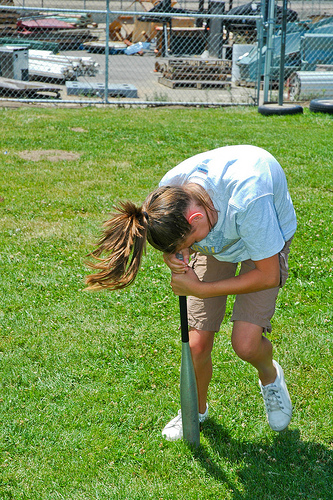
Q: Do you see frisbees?
A: No, there are no frisbees.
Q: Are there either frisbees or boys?
A: No, there are no frisbees or boys.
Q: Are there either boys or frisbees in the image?
A: No, there are no frisbees or boys.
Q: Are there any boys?
A: No, there are no boys.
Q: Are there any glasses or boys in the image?
A: No, there are no boys or glasses.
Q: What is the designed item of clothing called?
A: The clothing item is a shirt.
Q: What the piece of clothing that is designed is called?
A: The clothing item is a shirt.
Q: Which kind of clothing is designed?
A: The clothing is a shirt.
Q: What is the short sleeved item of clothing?
A: The clothing item is a shirt.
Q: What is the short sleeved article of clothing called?
A: The clothing item is a shirt.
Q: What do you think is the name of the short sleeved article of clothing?
A: The clothing item is a shirt.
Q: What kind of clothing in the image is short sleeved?
A: The clothing is a shirt.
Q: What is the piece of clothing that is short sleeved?
A: The clothing item is a shirt.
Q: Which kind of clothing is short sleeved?
A: The clothing is a shirt.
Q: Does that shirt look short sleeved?
A: Yes, the shirt is short sleeved.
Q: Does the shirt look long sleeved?
A: No, the shirt is short sleeved.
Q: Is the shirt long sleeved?
A: No, the shirt is short sleeved.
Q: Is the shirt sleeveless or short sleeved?
A: The shirt is short sleeved.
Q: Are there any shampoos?
A: No, there are no shampoos.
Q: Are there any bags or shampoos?
A: No, there are no shampoos or bags.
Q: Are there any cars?
A: No, there are no cars.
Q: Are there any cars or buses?
A: No, there are no cars or buses.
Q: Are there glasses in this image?
A: No, there are no glasses.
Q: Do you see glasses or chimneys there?
A: No, there are no glasses or chimneys.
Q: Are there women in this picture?
A: Yes, there is a woman.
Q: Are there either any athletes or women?
A: Yes, there is a woman.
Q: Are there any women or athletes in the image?
A: Yes, there is a woman.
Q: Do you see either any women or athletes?
A: Yes, there is a woman.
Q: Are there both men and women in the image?
A: No, there is a woman but no men.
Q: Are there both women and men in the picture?
A: No, there is a woman but no men.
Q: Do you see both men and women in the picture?
A: No, there is a woman but no men.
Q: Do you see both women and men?
A: No, there is a woman but no men.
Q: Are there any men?
A: No, there are no men.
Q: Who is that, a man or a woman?
A: That is a woman.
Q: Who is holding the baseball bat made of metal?
A: The woman is holding the baseball bat.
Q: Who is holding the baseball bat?
A: The woman is holding the baseball bat.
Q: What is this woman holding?
A: The woman is holding the baseball bat.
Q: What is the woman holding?
A: The woman is holding the baseball bat.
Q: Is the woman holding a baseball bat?
A: Yes, the woman is holding a baseball bat.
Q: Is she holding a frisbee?
A: No, the woman is holding a baseball bat.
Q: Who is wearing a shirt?
A: The woman is wearing a shirt.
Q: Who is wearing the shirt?
A: The woman is wearing a shirt.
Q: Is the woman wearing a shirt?
A: Yes, the woman is wearing a shirt.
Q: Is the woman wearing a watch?
A: No, the woman is wearing a shirt.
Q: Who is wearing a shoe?
A: The woman is wearing a shoe.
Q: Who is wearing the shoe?
A: The woman is wearing a shoe.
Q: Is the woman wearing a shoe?
A: Yes, the woman is wearing a shoe.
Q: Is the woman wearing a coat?
A: No, the woman is wearing a shoe.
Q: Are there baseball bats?
A: Yes, there is a baseball bat.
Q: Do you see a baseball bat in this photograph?
A: Yes, there is a baseball bat.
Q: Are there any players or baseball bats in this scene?
A: Yes, there is a baseball bat.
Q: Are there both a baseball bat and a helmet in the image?
A: No, there is a baseball bat but no helmets.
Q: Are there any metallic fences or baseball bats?
A: Yes, there is a metal baseball bat.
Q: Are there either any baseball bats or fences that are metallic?
A: Yes, the baseball bat is metallic.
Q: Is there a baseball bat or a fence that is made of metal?
A: Yes, the baseball bat is made of metal.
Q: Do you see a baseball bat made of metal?
A: Yes, there is a baseball bat that is made of metal.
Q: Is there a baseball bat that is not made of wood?
A: Yes, there is a baseball bat that is made of metal.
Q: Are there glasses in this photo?
A: No, there are no glasses.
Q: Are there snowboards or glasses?
A: No, there are no glasses or snowboards.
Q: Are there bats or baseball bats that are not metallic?
A: No, there is a baseball bat but it is metallic.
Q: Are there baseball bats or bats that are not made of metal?
A: No, there is a baseball bat but it is made of metal.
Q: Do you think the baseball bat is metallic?
A: Yes, the baseball bat is metallic.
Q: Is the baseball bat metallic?
A: Yes, the baseball bat is metallic.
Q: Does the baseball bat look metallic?
A: Yes, the baseball bat is metallic.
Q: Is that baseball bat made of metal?
A: Yes, the baseball bat is made of metal.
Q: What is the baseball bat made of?
A: The baseball bat is made of metal.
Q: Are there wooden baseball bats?
A: No, there is a baseball bat but it is metallic.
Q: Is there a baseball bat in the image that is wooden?
A: No, there is a baseball bat but it is metallic.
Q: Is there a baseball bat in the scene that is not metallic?
A: No, there is a baseball bat but it is metallic.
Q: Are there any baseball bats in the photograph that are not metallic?
A: No, there is a baseball bat but it is metallic.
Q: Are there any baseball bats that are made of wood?
A: No, there is a baseball bat but it is made of metal.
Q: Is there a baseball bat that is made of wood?
A: No, there is a baseball bat but it is made of metal.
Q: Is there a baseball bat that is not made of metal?
A: No, there is a baseball bat but it is made of metal.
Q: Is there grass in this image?
A: Yes, there is grass.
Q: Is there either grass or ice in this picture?
A: Yes, there is grass.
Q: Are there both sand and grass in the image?
A: No, there is grass but no sand.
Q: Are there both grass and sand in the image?
A: No, there is grass but no sand.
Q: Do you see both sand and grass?
A: No, there is grass but no sand.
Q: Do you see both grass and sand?
A: No, there is grass but no sand.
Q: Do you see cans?
A: No, there are no cans.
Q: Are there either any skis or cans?
A: No, there are no cans or skis.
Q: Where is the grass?
A: The grass is on the ground.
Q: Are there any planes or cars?
A: No, there are no cars or planes.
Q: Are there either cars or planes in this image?
A: No, there are no cars or planes.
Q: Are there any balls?
A: No, there are no balls.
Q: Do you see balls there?
A: No, there are no balls.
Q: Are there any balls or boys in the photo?
A: No, there are no balls or boys.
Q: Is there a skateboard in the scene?
A: No, there are no skateboards.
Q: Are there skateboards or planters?
A: No, there are no skateboards or planters.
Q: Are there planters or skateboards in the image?
A: No, there are no skateboards or planters.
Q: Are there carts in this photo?
A: No, there are no carts.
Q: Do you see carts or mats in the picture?
A: No, there are no carts or mats.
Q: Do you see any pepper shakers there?
A: No, there are no pepper shakers.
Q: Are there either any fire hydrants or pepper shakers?
A: No, there are no pepper shakers or fire hydrants.